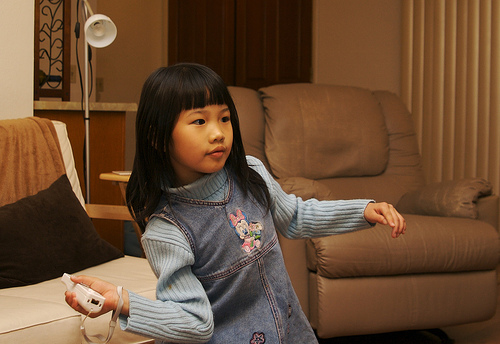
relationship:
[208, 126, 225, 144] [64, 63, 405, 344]
nose of a girl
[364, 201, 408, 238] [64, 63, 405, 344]
hand of a girl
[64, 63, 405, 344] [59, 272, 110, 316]
girl playing a game controller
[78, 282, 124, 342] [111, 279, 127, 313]
strap on girls right wrist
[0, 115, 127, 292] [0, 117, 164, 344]
blanket draped over back of chair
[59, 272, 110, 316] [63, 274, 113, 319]
game controller in hand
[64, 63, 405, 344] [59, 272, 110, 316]
girl holding game controller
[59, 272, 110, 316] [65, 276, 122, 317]
game controller in hand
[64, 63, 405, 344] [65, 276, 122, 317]
girl has hand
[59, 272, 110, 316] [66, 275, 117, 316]
game controller in hand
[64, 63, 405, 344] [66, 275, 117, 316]
girl has hand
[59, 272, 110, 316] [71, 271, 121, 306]
game controller in girl's hand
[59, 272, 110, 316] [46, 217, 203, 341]
game controller in hand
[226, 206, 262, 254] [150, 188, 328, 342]
minnie mouse on jumper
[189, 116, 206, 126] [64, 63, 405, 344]
eye on girl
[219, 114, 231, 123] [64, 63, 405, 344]
eye on girl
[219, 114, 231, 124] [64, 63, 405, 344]
eye on girl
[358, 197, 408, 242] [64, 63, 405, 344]
hand on girl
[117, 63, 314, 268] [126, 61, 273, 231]
girl has hair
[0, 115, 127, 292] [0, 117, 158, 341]
blanket draped over chair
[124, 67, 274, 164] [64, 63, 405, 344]
head of girl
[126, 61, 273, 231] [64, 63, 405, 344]
hair on girl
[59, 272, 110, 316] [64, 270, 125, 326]
game controller in hand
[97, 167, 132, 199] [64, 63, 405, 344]
table behind girl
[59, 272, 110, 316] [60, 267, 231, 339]
game controller in hand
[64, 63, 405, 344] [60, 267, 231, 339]
girl has hand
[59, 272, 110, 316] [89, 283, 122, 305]
game controller in hand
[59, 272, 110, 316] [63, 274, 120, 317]
game controller in girl's hand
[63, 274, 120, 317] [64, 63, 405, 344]
girl's hand of girl